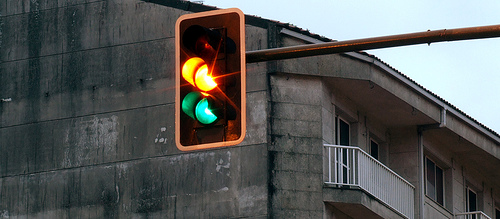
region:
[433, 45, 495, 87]
the sky is blue in color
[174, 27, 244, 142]
this is a traffic light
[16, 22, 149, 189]
this is a building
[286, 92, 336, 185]
this is the wall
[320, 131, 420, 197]
this is the balcony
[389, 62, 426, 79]
this is the roof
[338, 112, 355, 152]
this is a door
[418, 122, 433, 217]
this is a pipe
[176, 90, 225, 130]
a green light at a stop light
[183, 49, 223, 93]
a yellow light on a stop light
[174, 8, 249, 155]
a stop light on a metal pole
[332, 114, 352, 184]
a door on a balcony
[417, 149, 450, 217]
a door on a balcony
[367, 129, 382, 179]
a window on a wall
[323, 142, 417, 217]
a metal railing on a balcony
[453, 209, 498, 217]
a metal railing on a balcony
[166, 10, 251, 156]
a stop light with green and yellow lights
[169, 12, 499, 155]
a stop light attached to a pole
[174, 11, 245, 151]
this is a traffic light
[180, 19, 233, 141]
the lights are on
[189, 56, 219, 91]
the light is orange in color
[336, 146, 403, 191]
this is the balcon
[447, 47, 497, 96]
this is the sky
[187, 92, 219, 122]
the light is green in color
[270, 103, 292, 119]
weathered print on building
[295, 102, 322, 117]
weathered print on building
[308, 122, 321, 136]
weathered print on building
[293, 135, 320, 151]
weathered print on building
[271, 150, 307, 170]
weathered print on building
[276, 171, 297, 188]
weathered print on building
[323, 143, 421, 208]
a white railing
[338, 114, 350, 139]
a window on the building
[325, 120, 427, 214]
a balcony on the building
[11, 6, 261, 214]
a cement building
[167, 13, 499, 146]
a street light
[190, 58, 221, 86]
a yellow light on a street light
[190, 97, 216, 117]
a green light on a street light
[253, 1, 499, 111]
the sky behind the building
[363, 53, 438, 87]
the roof of the building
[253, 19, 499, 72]
the black pole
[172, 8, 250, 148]
Traffic light signal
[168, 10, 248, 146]
Traffic signal turning from green to yellow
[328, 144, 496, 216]
Railing on balconies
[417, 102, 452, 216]
Gutter on building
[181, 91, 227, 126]
Green light on traffic signal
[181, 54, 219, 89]
Yellow light on traffic signal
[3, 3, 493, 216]
Grey building behind traffic signal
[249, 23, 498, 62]
Pole holding traffic signal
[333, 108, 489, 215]
Doors to balconies in grey building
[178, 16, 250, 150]
Two lights lit on a traffic signal